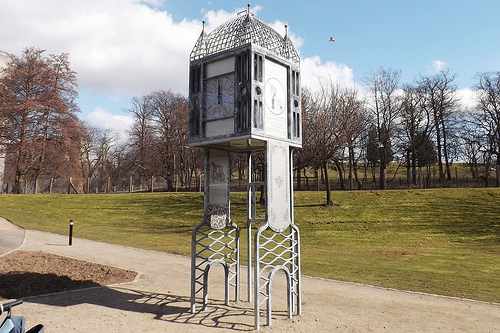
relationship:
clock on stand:
[201, 71, 234, 122] [185, 2, 306, 315]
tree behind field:
[131, 105, 157, 189] [59, 189, 496, 278]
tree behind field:
[308, 106, 351, 206] [59, 189, 496, 278]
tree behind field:
[358, 90, 392, 183] [59, 189, 496, 278]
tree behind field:
[401, 112, 436, 178] [59, 189, 496, 278]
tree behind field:
[424, 81, 443, 180] [59, 189, 496, 278]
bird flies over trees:
[325, 32, 336, 43] [0, 44, 499, 194]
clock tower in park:
[186, 7, 313, 299] [290, 169, 460, 322]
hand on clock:
[217, 79, 221, 104] [203, 71, 237, 121]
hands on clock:
[270, 94, 277, 111] [260, 76, 287, 115]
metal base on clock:
[185, 220, 302, 325] [183, 57, 301, 145]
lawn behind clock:
[0, 183, 499, 302] [202, 73, 237, 118]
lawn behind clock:
[0, 183, 499, 302] [259, 73, 289, 115]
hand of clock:
[215, 77, 225, 109] [204, 68, 245, 120]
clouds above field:
[101, 21, 159, 66] [327, 185, 498, 297]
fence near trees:
[22, 172, 201, 191] [1, 44, 201, 188]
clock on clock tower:
[201, 72, 234, 122] [188, 3, 303, 329]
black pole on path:
[60, 215, 78, 247] [84, 240, 438, 331]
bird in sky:
[328, 36, 335, 42] [1, 2, 498, 168]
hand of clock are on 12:
[217, 79, 221, 104] [214, 74, 224, 85]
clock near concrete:
[201, 71, 234, 122] [21, 246, 482, 331]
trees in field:
[295, 99, 485, 148] [2, 166, 498, 240]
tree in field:
[394, 97, 436, 186] [12, 159, 499, 269]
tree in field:
[1, 46, 91, 191] [12, 159, 499, 269]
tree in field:
[327, 86, 372, 187] [12, 159, 499, 269]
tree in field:
[461, 71, 499, 188] [12, 159, 499, 269]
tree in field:
[128, 90, 205, 191] [12, 159, 499, 269]